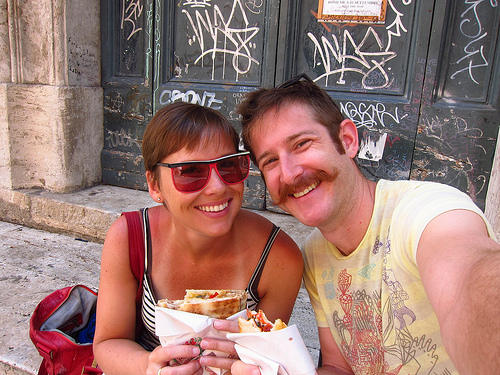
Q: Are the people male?
A: No, they are both male and female.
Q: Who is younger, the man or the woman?
A: The man is younger than the woman.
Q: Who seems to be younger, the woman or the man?
A: The man is younger than the woman.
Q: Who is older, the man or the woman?
A: The woman is older than the man.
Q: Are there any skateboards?
A: No, there are no skateboards.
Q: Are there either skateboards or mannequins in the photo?
A: No, there are no skateboards or mannequins.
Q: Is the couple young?
A: Yes, the couple is young.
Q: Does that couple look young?
A: Yes, the couple is young.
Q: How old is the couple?
A: The couple is young.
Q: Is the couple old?
A: No, the couple is young.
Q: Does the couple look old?
A: No, the couple is young.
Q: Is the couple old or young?
A: The couple is young.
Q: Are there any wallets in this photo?
A: No, there are no wallets.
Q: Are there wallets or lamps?
A: No, there are no wallets or lamps.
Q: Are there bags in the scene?
A: Yes, there is a bag.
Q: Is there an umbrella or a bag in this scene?
A: Yes, there is a bag.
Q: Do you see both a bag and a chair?
A: No, there is a bag but no chairs.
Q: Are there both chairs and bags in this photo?
A: No, there is a bag but no chairs.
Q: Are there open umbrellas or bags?
A: Yes, there is an open bag.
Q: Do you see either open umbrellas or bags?
A: Yes, there is an open bag.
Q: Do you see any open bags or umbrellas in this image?
A: Yes, there is an open bag.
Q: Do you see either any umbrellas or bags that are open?
A: Yes, the bag is open.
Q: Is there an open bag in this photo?
A: Yes, there is an open bag.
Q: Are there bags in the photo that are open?
A: Yes, there is a bag that is open.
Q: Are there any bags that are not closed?
A: Yes, there is a open bag.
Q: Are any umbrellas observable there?
A: No, there are no umbrellas.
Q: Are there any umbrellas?
A: No, there are no umbrellas.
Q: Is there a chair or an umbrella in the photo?
A: No, there are no umbrellas or chairs.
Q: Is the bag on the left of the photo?
A: Yes, the bag is on the left of the image.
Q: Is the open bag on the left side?
A: Yes, the bag is on the left of the image.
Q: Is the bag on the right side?
A: No, the bag is on the left of the image.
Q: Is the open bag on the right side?
A: No, the bag is on the left of the image.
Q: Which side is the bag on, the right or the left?
A: The bag is on the left of the image.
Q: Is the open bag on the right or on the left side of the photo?
A: The bag is on the left of the image.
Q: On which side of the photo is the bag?
A: The bag is on the left of the image.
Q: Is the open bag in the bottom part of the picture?
A: Yes, the bag is in the bottom of the image.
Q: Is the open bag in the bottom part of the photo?
A: Yes, the bag is in the bottom of the image.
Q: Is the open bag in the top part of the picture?
A: No, the bag is in the bottom of the image.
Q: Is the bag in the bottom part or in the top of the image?
A: The bag is in the bottom of the image.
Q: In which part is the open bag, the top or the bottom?
A: The bag is in the bottom of the image.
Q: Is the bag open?
A: Yes, the bag is open.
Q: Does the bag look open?
A: Yes, the bag is open.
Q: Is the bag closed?
A: No, the bag is open.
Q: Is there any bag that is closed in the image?
A: No, there is a bag but it is open.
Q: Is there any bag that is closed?
A: No, there is a bag but it is open.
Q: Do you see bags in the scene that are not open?
A: No, there is a bag but it is open.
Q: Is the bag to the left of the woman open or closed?
A: The bag is open.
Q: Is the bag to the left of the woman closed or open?
A: The bag is open.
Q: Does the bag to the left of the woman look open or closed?
A: The bag is open.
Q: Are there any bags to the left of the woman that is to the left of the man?
A: Yes, there is a bag to the left of the woman.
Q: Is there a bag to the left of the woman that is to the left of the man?
A: Yes, there is a bag to the left of the woman.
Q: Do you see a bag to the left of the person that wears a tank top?
A: Yes, there is a bag to the left of the woman.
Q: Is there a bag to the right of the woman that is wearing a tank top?
A: No, the bag is to the left of the woman.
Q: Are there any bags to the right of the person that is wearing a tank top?
A: No, the bag is to the left of the woman.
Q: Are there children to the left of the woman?
A: No, there is a bag to the left of the woman.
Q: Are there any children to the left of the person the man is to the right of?
A: No, there is a bag to the left of the woman.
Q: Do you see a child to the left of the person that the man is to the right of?
A: No, there is a bag to the left of the woman.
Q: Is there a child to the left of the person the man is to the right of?
A: No, there is a bag to the left of the woman.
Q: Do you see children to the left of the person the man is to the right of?
A: No, there is a bag to the left of the woman.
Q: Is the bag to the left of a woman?
A: Yes, the bag is to the left of a woman.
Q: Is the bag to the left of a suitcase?
A: No, the bag is to the left of a woman.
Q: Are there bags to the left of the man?
A: Yes, there is a bag to the left of the man.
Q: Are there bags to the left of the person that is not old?
A: Yes, there is a bag to the left of the man.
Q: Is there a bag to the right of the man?
A: No, the bag is to the left of the man.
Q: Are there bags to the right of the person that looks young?
A: No, the bag is to the left of the man.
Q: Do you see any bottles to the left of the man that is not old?
A: No, there is a bag to the left of the man.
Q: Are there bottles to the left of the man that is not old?
A: No, there is a bag to the left of the man.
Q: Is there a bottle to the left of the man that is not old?
A: No, there is a bag to the left of the man.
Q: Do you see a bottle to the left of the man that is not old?
A: No, there is a bag to the left of the man.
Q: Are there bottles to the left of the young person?
A: No, there is a bag to the left of the man.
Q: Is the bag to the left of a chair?
A: No, the bag is to the left of the man.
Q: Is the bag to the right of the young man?
A: No, the bag is to the left of the man.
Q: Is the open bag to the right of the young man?
A: No, the bag is to the left of the man.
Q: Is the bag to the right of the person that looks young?
A: No, the bag is to the left of the man.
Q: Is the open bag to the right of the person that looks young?
A: No, the bag is to the left of the man.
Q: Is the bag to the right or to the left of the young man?
A: The bag is to the left of the man.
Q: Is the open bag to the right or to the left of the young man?
A: The bag is to the left of the man.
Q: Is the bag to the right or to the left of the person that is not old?
A: The bag is to the left of the man.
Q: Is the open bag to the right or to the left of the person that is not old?
A: The bag is to the left of the man.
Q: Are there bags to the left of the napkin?
A: Yes, there is a bag to the left of the napkin.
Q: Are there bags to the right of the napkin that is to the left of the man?
A: No, the bag is to the left of the napkin.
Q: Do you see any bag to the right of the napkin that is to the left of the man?
A: No, the bag is to the left of the napkin.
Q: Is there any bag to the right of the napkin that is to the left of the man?
A: No, the bag is to the left of the napkin.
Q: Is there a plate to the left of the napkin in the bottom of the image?
A: No, there is a bag to the left of the napkin.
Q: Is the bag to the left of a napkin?
A: Yes, the bag is to the left of a napkin.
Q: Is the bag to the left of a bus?
A: No, the bag is to the left of a napkin.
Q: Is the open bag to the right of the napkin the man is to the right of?
A: No, the bag is to the left of the napkin.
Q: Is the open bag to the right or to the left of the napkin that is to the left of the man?
A: The bag is to the left of the napkin.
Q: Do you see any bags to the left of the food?
A: Yes, there is a bag to the left of the food.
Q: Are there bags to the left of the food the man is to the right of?
A: Yes, there is a bag to the left of the food.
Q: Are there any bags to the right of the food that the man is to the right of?
A: No, the bag is to the left of the food.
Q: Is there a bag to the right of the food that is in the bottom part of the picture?
A: No, the bag is to the left of the food.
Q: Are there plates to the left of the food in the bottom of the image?
A: No, there is a bag to the left of the food.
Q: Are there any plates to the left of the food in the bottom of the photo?
A: No, there is a bag to the left of the food.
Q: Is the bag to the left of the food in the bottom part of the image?
A: Yes, the bag is to the left of the food.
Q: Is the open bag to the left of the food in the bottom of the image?
A: Yes, the bag is to the left of the food.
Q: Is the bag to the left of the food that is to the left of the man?
A: Yes, the bag is to the left of the food.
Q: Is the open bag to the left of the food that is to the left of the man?
A: Yes, the bag is to the left of the food.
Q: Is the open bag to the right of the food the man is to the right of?
A: No, the bag is to the left of the food.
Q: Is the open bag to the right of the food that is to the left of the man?
A: No, the bag is to the left of the food.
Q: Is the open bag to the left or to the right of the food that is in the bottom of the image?
A: The bag is to the left of the food.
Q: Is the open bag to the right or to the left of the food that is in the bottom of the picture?
A: The bag is to the left of the food.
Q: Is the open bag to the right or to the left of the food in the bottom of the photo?
A: The bag is to the left of the food.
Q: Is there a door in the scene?
A: Yes, there is a door.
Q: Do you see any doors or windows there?
A: Yes, there is a door.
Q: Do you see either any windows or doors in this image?
A: Yes, there is a door.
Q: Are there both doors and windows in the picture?
A: No, there is a door but no windows.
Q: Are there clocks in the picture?
A: No, there are no clocks.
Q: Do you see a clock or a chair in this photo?
A: No, there are no clocks or chairs.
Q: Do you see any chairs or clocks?
A: No, there are no clocks or chairs.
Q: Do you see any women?
A: Yes, there is a woman.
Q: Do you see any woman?
A: Yes, there is a woman.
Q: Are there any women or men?
A: Yes, there is a woman.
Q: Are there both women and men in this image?
A: Yes, there are both a woman and a man.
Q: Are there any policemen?
A: No, there are no policemen.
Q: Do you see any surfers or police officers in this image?
A: No, there are no police officers or surfers.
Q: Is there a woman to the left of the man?
A: Yes, there is a woman to the left of the man.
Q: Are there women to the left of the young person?
A: Yes, there is a woman to the left of the man.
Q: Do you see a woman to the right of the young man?
A: No, the woman is to the left of the man.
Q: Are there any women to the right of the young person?
A: No, the woman is to the left of the man.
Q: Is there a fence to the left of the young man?
A: No, there is a woman to the left of the man.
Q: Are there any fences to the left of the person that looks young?
A: No, there is a woman to the left of the man.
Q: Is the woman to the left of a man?
A: Yes, the woman is to the left of a man.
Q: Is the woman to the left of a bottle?
A: No, the woman is to the left of a man.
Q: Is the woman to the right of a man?
A: No, the woman is to the left of a man.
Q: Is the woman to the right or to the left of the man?
A: The woman is to the left of the man.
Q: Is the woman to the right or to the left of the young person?
A: The woman is to the left of the man.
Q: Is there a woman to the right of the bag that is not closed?
A: Yes, there is a woman to the right of the bag.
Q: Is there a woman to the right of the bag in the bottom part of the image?
A: Yes, there is a woman to the right of the bag.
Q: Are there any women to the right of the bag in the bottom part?
A: Yes, there is a woman to the right of the bag.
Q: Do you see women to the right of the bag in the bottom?
A: Yes, there is a woman to the right of the bag.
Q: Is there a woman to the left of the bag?
A: No, the woman is to the right of the bag.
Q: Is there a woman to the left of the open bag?
A: No, the woman is to the right of the bag.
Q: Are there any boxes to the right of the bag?
A: No, there is a woman to the right of the bag.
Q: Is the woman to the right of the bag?
A: Yes, the woman is to the right of the bag.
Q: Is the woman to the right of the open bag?
A: Yes, the woman is to the right of the bag.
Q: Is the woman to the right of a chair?
A: No, the woman is to the right of the bag.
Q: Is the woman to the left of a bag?
A: No, the woman is to the right of a bag.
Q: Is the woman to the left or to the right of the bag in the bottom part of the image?
A: The woman is to the right of the bag.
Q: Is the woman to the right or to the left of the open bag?
A: The woman is to the right of the bag.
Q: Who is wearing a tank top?
A: The woman is wearing a tank top.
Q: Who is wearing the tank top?
A: The woman is wearing a tank top.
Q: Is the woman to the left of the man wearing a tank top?
A: Yes, the woman is wearing a tank top.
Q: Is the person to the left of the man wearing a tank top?
A: Yes, the woman is wearing a tank top.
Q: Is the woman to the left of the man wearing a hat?
A: No, the woman is wearing a tank top.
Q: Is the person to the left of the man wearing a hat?
A: No, the woman is wearing a tank top.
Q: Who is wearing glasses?
A: The woman is wearing glasses.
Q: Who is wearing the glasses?
A: The woman is wearing glasses.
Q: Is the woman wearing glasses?
A: Yes, the woman is wearing glasses.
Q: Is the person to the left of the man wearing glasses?
A: Yes, the woman is wearing glasses.